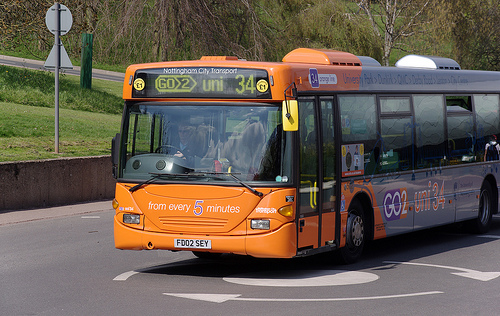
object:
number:
[193, 199, 203, 215]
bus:
[110, 48, 499, 262]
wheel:
[341, 195, 370, 262]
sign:
[42, 0, 76, 70]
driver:
[173, 122, 192, 158]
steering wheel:
[154, 145, 183, 154]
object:
[208, 157, 226, 172]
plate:
[174, 238, 212, 249]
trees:
[145, 11, 265, 50]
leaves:
[439, 29, 473, 56]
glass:
[163, 123, 242, 169]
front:
[115, 60, 295, 256]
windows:
[356, 91, 467, 177]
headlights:
[246, 217, 273, 232]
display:
[152, 65, 256, 98]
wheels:
[477, 181, 493, 233]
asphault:
[47, 220, 127, 311]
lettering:
[201, 74, 256, 94]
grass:
[15, 141, 25, 147]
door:
[294, 94, 340, 253]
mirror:
[283, 99, 298, 131]